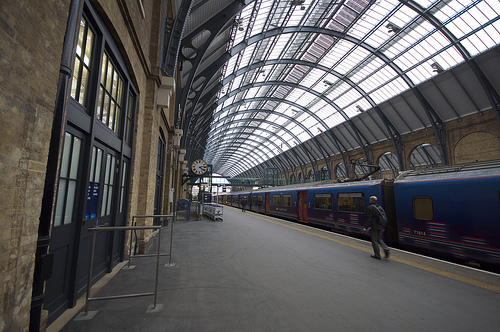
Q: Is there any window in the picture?
A: Yes, there is a window.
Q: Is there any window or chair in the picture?
A: Yes, there is a window.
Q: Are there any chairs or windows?
A: Yes, there is a window.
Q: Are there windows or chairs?
A: Yes, there is a window.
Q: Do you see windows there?
A: Yes, there is a window.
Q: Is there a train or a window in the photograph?
A: Yes, there is a window.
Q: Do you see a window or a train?
A: Yes, there is a window.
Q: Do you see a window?
A: Yes, there is a window.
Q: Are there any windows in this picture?
A: Yes, there is a window.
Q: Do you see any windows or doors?
A: Yes, there is a window.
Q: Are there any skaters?
A: No, there are no skaters.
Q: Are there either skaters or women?
A: No, there are no skaters or women.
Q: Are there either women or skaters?
A: No, there are no skaters or women.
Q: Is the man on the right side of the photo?
A: Yes, the man is on the right of the image.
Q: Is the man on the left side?
A: No, the man is on the right of the image.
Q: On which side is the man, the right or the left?
A: The man is on the right of the image.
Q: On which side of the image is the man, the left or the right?
A: The man is on the right of the image.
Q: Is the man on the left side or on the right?
A: The man is on the right of the image.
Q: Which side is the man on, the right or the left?
A: The man is on the right of the image.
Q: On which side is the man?
A: The man is on the right of the image.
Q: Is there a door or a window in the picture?
A: Yes, there is a window.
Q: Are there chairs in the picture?
A: No, there are no chairs.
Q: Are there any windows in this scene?
A: Yes, there is a window.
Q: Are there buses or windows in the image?
A: Yes, there is a window.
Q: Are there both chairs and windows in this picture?
A: No, there is a window but no chairs.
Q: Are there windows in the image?
A: Yes, there is a window.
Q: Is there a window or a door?
A: Yes, there is a window.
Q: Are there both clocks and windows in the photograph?
A: Yes, there are both a window and a clock.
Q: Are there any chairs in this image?
A: No, there are no chairs.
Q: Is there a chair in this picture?
A: No, there are no chairs.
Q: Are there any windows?
A: Yes, there is a window.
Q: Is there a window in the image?
A: Yes, there is a window.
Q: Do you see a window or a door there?
A: Yes, there is a window.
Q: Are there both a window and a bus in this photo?
A: No, there is a window but no buses.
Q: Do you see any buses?
A: No, there are no buses.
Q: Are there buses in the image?
A: No, there are no buses.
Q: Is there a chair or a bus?
A: No, there are no buses or chairs.